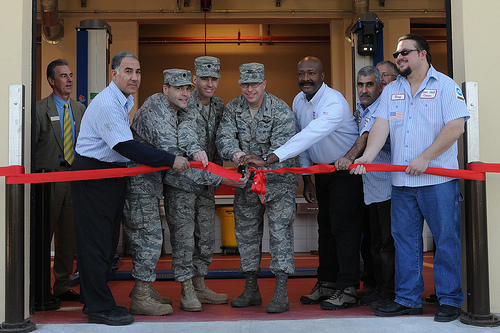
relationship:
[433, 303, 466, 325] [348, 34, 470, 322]
shoe on employess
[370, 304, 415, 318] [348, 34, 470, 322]
shoe on employess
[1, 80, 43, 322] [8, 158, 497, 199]
post holds ribbon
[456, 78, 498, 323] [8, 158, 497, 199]
post holds ribbon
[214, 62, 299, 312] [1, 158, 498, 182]
man cutting ribbon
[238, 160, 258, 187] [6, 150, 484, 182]
scissors cutting ribbon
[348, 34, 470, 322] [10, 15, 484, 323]
employess owns store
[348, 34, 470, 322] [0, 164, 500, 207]
employess behind a ribbon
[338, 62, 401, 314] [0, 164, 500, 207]
guys behind a ribbon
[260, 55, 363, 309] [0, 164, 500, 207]
guys behind a ribbon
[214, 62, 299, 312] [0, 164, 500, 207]
man behind a ribbon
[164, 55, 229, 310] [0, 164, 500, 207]
man behind a ribbon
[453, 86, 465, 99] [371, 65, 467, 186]
patch on a blue shirt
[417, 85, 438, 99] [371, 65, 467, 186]
patch on a blue shirt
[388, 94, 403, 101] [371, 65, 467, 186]
patch on a blue shirt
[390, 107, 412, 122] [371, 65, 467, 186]
patch on a blue shirt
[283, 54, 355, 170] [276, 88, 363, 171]
man in shirt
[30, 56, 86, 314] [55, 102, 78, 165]
civilian in tie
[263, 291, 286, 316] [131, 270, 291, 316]
feet in boots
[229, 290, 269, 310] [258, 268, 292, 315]
feet in boots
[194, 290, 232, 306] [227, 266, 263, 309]
feet in boots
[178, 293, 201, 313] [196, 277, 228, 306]
feet in boots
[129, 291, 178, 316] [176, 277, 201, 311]
feet in boots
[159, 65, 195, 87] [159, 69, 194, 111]
hats on heads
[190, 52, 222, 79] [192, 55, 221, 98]
hats on heads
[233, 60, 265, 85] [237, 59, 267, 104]
hats on heads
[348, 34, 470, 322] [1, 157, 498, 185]
employess holding ribbon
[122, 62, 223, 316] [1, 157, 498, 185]
men holding ribbon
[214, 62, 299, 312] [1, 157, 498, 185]
man holding ribbon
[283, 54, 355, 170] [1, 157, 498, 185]
man holding ribbon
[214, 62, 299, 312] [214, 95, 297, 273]
man wearing a uniform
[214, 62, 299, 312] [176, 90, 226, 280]
man wearing a uniform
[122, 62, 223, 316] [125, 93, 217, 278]
men wearing a uniform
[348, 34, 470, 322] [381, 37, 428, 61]
employess wearing sunglasses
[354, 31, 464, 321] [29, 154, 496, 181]
they cutting a ribbon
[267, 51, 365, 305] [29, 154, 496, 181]
they cutting a ribbon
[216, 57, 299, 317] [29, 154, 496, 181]
they cutting a ribbon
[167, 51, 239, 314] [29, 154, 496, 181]
they cutting a ribbon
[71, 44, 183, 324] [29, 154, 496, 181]
they cutting a ribbon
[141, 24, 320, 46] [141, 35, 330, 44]
pipe connected to pipe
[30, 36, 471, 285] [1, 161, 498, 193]
they are enjoying ribbon